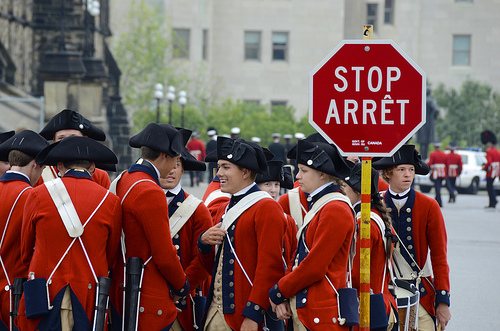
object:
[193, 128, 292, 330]
person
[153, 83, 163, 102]
street light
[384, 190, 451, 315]
red jacket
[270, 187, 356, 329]
red jacket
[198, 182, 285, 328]
red jacket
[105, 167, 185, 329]
red jacket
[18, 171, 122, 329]
red jacket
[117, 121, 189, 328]
person/jacket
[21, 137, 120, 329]
person/jacket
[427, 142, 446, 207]
person/jacket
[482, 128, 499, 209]
person/jacket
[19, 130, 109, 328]
person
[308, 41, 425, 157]
sign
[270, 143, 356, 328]
person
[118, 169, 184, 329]
uniform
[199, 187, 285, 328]
uniform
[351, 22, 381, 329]
pole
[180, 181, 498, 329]
street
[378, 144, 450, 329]
person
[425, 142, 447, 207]
person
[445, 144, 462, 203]
person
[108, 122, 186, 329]
person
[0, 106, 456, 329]
group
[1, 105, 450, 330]
soldiers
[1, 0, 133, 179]
building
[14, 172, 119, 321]
jacket